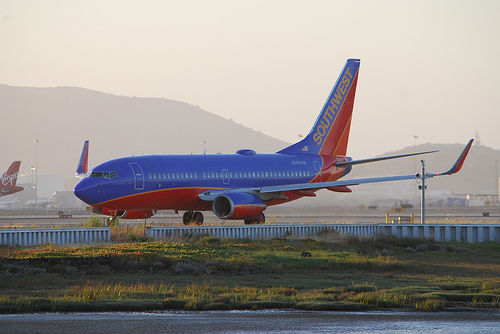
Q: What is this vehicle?
A: Airplane.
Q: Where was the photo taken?
A: Airport.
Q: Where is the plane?
A: On the ground.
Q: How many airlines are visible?
A: Two.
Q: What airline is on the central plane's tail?
A: SOUTHWEST.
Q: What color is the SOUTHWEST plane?
A: Blue.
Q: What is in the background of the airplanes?
A: Mountains.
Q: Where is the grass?
A: Next to the plane.